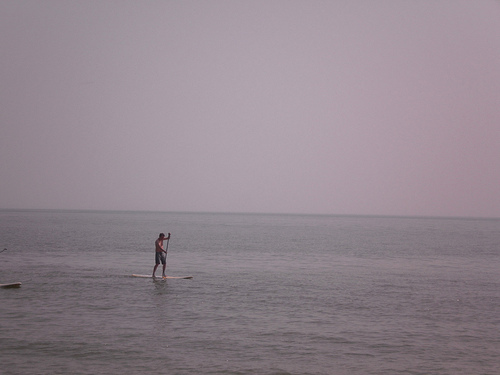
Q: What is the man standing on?
A: A paddleboard.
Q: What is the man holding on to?
A: A paddle.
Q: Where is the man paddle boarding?
A: In the ocean.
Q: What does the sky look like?
A: Gray and cloudy.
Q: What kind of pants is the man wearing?
A: Shorts.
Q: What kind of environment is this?
A: Ocean.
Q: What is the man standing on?
A: Surfboard.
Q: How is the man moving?
A: With a paddle.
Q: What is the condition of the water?
A: Flat.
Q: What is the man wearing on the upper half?
A: He is shirtless.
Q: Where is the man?
A: On the water.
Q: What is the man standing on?
A: A board.